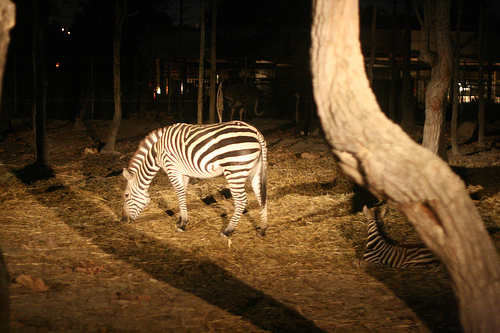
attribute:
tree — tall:
[310, 0, 499, 332]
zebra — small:
[122, 130, 273, 230]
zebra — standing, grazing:
[133, 79, 334, 278]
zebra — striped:
[81, 111, 323, 223]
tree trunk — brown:
[323, 71, 495, 278]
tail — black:
[250, 149, 275, 213]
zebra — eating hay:
[115, 125, 245, 237]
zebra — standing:
[113, 91, 299, 256]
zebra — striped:
[68, 109, 275, 240]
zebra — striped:
[95, 110, 281, 244]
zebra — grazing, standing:
[95, 103, 288, 248]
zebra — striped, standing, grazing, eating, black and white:
[120, 120, 268, 236]